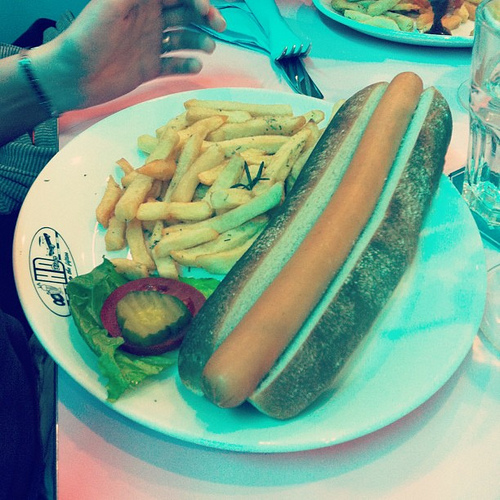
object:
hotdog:
[200, 71, 423, 408]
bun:
[177, 72, 453, 421]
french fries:
[96, 99, 347, 280]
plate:
[10, 87, 489, 456]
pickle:
[115, 289, 191, 347]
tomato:
[101, 276, 207, 356]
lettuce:
[64, 254, 222, 403]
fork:
[244, 0, 313, 61]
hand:
[50, 0, 227, 113]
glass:
[461, 0, 500, 249]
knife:
[274, 54, 325, 100]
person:
[0, 1, 227, 500]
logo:
[28, 227, 77, 317]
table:
[54, 0, 499, 500]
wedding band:
[160, 33, 172, 56]